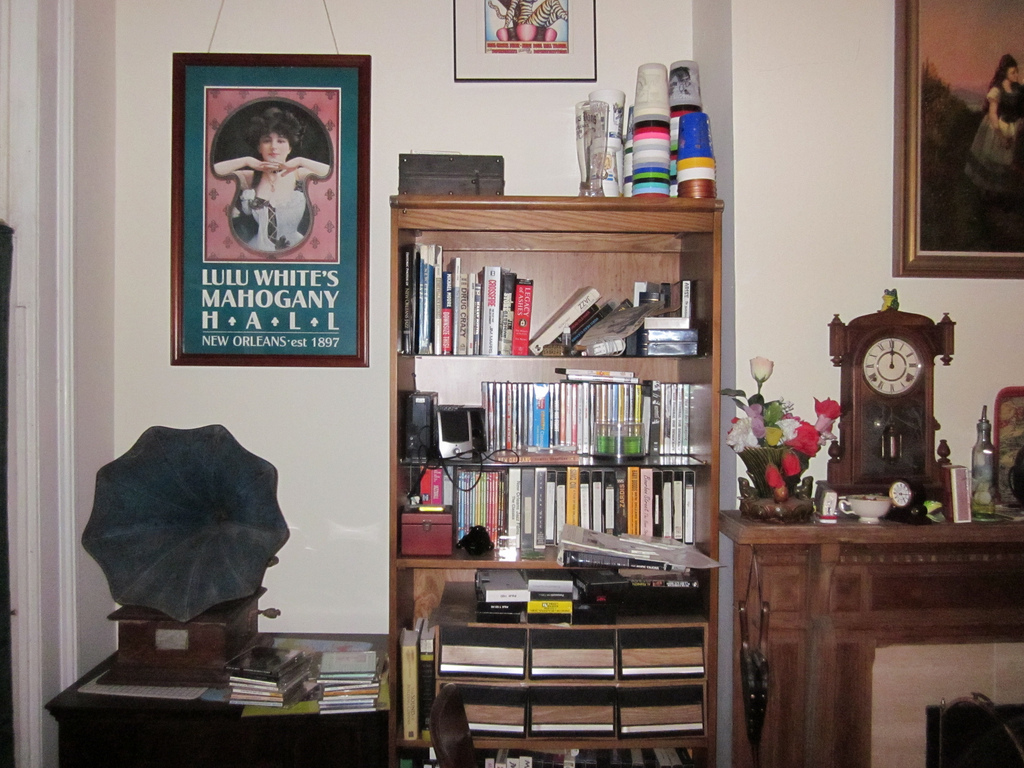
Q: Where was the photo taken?
A: In a living room.